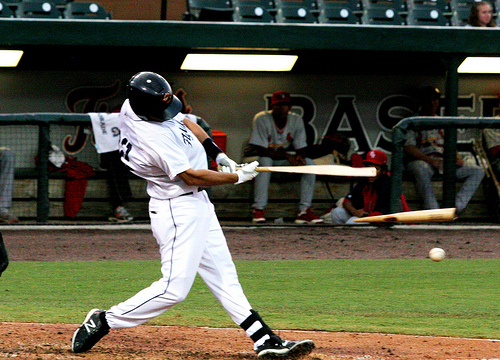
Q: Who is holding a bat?
A: The man.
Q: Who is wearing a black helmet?
A: A man.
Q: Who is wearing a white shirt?
A: A man.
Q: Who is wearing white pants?
A: A man.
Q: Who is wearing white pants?
A: The baseball player.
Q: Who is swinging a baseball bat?
A: The player.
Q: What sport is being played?
A: Baseball.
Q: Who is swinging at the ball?
A: Batter.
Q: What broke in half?
A: The bat.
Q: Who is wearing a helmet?
A: The batter.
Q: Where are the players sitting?
A: In the dugout.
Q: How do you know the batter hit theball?
A: The bat broke.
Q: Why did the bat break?
A: It hit the ball.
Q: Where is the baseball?
A: In mid air.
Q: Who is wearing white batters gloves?
A: The hitter.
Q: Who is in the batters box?
A: The hitter.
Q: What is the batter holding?
A: A baseball bat.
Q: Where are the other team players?
A: In the dugout.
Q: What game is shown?
A: Baseball.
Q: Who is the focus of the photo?
A: Batter.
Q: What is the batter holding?
A: Bat.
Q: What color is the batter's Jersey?
A: White.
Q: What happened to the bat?
A: Broke.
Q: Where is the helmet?
A: Head of batter.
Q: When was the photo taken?
A: Daytime.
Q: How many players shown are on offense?
A: One.